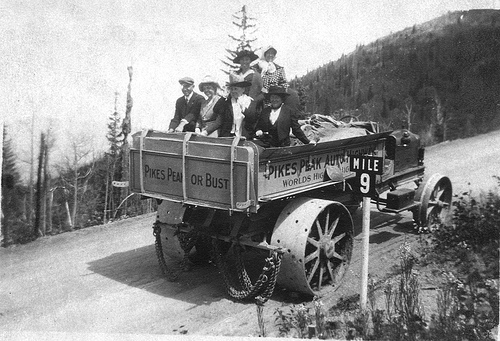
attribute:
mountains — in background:
[1, 4, 492, 181]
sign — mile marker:
[351, 152, 410, 212]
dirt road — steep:
[2, 133, 498, 338]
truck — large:
[60, 112, 451, 316]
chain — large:
[211, 239, 282, 307]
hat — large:
[232, 50, 255, 60]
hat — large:
[226, 68, 254, 85]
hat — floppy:
[240, 46, 255, 58]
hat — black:
[264, 82, 291, 100]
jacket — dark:
[171, 93, 207, 130]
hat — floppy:
[194, 72, 225, 97]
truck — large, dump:
[134, 120, 464, 304]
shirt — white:
[270, 103, 282, 129]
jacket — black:
[255, 95, 295, 145]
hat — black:
[260, 83, 292, 96]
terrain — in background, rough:
[9, 16, 493, 221]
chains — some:
[199, 240, 283, 306]